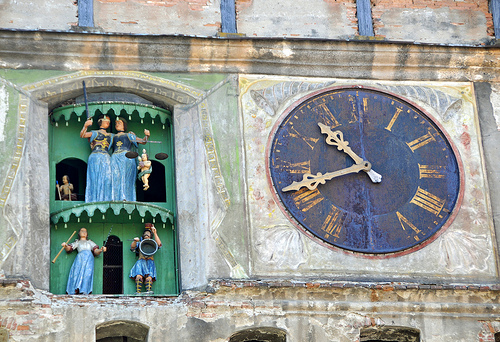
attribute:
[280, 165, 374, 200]
hand — small, large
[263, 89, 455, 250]
clock — blue, gold, ornate, large, unusual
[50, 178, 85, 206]
boy — sitting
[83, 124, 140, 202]
ladies — hugging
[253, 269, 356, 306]
wall — stone, green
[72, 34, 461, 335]
building — green, stone, classic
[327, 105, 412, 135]
numerals — gold, roman, fading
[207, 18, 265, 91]
paint — chipping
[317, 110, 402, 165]
pointer — ornate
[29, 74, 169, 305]
figurines — looking, green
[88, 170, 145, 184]
outfits — blue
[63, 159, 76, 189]
door — black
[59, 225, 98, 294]
woman — Statue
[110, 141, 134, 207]
man — statue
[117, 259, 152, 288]
statue — small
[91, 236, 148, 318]
windows — openings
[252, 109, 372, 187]
10:42 — time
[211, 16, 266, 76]
stone — chipping